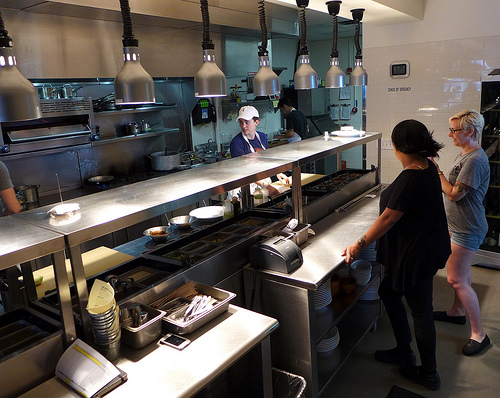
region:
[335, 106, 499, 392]
People in a restaurant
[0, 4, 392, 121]
Seven lights hanging from the ceiling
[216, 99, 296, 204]
Woman serving food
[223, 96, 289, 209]
Woman has a white cap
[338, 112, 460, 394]
Woman wears white cloths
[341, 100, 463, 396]
Woman has black hair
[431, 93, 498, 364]
Woman is blond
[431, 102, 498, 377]
Woman wears short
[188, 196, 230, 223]
White dish on the counter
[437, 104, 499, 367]
Woman wears glasses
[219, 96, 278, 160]
cook in a commercial kitchen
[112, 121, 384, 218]
steel shelf for plates of cooked food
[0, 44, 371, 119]
metal lamps over shelf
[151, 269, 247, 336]
metal pans with utensils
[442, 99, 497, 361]
woman with blonde hair and shorts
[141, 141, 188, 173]
white pot with utensil in it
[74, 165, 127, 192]
frying pan on stove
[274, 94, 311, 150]
cook in white apron facing wall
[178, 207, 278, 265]
ingredients in containers for meals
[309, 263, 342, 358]
clean plates in stacks on shelves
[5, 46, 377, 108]
Restaurant warming lights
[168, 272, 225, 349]
silverware in a stainless steel container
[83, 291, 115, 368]
stacked stainless steel cups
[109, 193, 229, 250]
different sizes stainless steel bowles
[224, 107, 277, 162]
white hat and apron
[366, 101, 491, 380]
two women giving their food orders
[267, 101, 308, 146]
cook preparing food orders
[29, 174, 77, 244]
tickets with food orders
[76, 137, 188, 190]
pots of food sitting on stove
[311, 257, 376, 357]
plates and bowls for food orders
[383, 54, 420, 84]
clock on a wall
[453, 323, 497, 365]
shoe on a foot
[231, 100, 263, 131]
white hat on a head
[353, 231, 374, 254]
tattoo on an arm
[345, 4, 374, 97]
light on a ceiling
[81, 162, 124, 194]
pan on a stove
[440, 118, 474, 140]
glasses on a face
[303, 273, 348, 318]
plates on a shelf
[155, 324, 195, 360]
phone on a table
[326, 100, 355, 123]
two clipboard on a wall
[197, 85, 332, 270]
person cooking food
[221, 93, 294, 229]
person wearing a white hat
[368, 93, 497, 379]
woman watching food being prepared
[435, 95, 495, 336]
a woman in a gray shirt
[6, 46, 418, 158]
row of lights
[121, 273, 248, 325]
tray of dining utensils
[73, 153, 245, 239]
dishes used for cooking food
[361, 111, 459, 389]
woman wearing all black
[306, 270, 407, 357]
white plates in a stack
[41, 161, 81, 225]
ticket holder